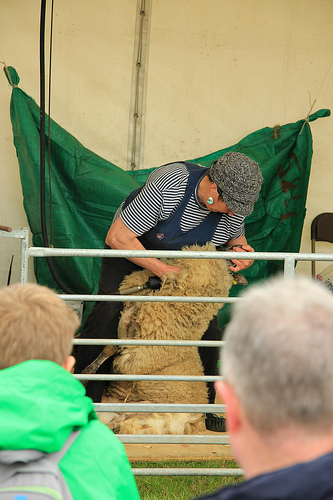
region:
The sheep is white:
[90, 239, 248, 439]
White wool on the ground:
[107, 399, 201, 450]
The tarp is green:
[7, 74, 325, 307]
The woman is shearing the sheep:
[69, 146, 266, 399]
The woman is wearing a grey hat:
[204, 150, 265, 227]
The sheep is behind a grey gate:
[10, 225, 328, 473]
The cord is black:
[30, 94, 140, 298]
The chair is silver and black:
[300, 206, 330, 276]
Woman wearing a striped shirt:
[110, 156, 269, 262]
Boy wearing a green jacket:
[2, 281, 143, 489]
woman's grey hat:
[208, 151, 266, 218]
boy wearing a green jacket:
[3, 285, 145, 496]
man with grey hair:
[216, 273, 331, 498]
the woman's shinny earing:
[205, 195, 214, 205]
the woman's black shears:
[146, 270, 168, 292]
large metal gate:
[8, 224, 331, 456]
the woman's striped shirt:
[110, 165, 252, 268]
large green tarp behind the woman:
[3, 56, 331, 365]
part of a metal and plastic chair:
[308, 208, 331, 296]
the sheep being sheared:
[106, 243, 244, 452]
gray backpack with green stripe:
[1, 411, 96, 498]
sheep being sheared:
[78, 241, 248, 434]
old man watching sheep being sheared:
[194, 272, 331, 498]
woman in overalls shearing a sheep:
[70, 149, 260, 430]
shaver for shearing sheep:
[38, 0, 161, 294]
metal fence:
[0, 225, 331, 472]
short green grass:
[127, 458, 245, 497]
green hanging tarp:
[2, 63, 328, 366]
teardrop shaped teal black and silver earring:
[206, 193, 214, 203]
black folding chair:
[310, 211, 332, 280]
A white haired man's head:
[232, 286, 329, 429]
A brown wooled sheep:
[126, 253, 222, 449]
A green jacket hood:
[4, 373, 74, 453]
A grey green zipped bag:
[10, 451, 58, 498]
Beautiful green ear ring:
[209, 195, 212, 205]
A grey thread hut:
[210, 154, 266, 212]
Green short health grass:
[145, 478, 189, 494]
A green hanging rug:
[60, 143, 98, 256]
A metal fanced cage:
[24, 158, 332, 341]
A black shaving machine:
[142, 277, 166, 286]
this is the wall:
[196, 25, 253, 93]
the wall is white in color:
[175, 2, 238, 49]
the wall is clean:
[186, 15, 234, 80]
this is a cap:
[214, 155, 258, 210]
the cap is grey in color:
[223, 159, 245, 187]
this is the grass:
[157, 477, 180, 498]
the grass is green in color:
[151, 477, 177, 498]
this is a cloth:
[59, 161, 96, 214]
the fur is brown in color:
[149, 307, 194, 333]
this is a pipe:
[36, 106, 54, 227]